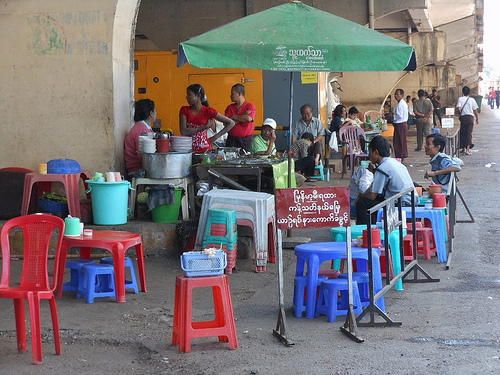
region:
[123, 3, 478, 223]
people clustered around a green umbrella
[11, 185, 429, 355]
empty chairs, stools and tables within a railing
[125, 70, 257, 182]
two women and a man behind a table and pot with dishes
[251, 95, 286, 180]
man seated behind table touching face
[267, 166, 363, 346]
curved white writing on elevated red sign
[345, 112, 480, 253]
two seated men facing the building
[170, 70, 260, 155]
man and woman in red facing same direction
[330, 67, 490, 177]
people seated or walking in the area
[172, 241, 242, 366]
blue basket on red stool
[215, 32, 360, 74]
white writing on the side of umbrella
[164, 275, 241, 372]
this is a red stool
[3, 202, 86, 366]
a red plastic chair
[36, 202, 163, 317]
a red plastic table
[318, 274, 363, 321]
a small blue chair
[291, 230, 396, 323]
a small blue table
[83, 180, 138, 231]
this is a bucket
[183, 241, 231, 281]
this is a basket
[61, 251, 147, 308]
these are blue chairs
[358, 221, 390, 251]
a single red bucket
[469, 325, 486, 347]
this is the concrete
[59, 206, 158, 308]
a small red plastic table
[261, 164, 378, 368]
a red and white business sign on the ground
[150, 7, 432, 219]
a green umbrella open on sidewalk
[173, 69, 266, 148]
two people in red shirts looking to the left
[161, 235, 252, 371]
red plastic stool with blue basket on top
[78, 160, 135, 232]
a baby blue bucket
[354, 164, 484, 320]
two metal guard rails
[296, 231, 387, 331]
blue plastic table and chairs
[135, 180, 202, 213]
a green bucket with rags in it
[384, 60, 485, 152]
people walking on the sidewalk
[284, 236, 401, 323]
a blue plastic table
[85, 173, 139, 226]
a light blue plastic bucket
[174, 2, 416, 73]
a large green umbrella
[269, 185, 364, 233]
a red sign at a street restaurant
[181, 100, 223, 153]
a woman in a red shirt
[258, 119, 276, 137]
a cap on a man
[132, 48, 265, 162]
a yellow wall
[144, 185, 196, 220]
a plastic green bucket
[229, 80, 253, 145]
a man in a red shirt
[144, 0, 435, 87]
Large green sun umbrella.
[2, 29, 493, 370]
Photo taken during the day.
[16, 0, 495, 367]
Photo taken at an open air market.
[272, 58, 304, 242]
Pole holding up the umbrella.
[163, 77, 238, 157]
A woman with a red shirt standing.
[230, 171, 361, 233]
Foreign writing on the sign.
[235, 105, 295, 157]
One man in a green shirt.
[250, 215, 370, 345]
Two posts holding up the sign.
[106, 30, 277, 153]
Part of the wall is yellow.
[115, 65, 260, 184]
Three people in red shirts.